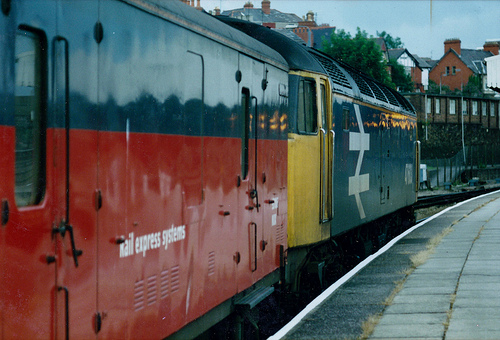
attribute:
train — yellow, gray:
[181, 0, 488, 322]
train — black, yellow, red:
[1, 0, 444, 325]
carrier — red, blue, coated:
[106, 8, 300, 303]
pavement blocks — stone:
[278, 189, 498, 339]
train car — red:
[7, 4, 285, 339]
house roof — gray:
[459, 47, 484, 72]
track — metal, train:
[415, 187, 499, 209]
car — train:
[215, 14, 423, 276]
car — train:
[2, 4, 278, 338]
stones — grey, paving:
[367, 199, 498, 337]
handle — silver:
[316, 127, 338, 221]